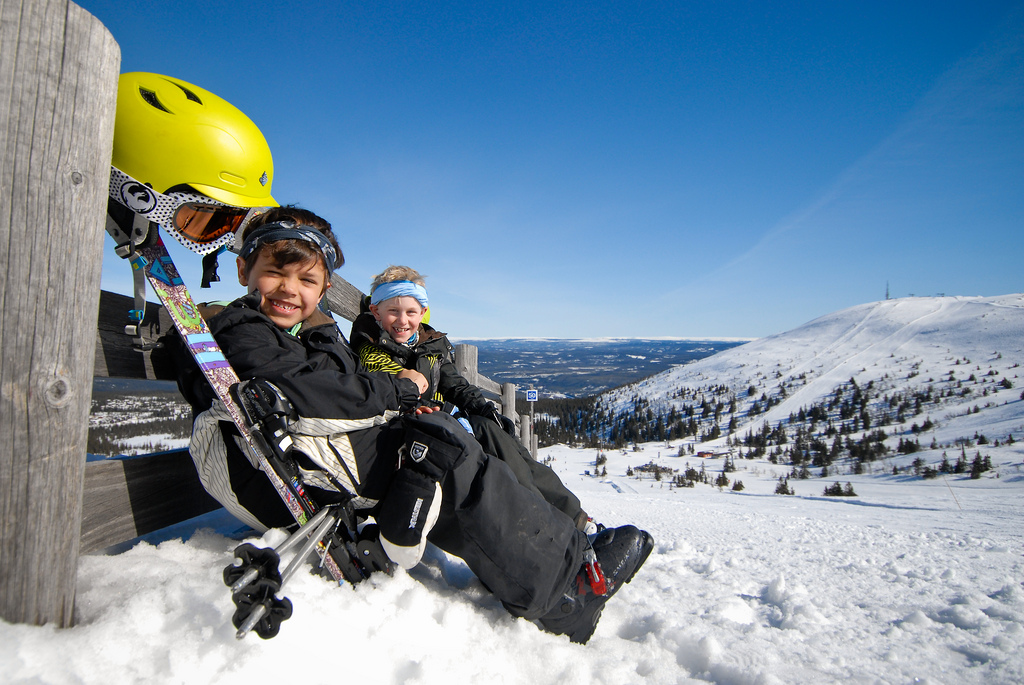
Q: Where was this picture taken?
A: On a snowy mountain.